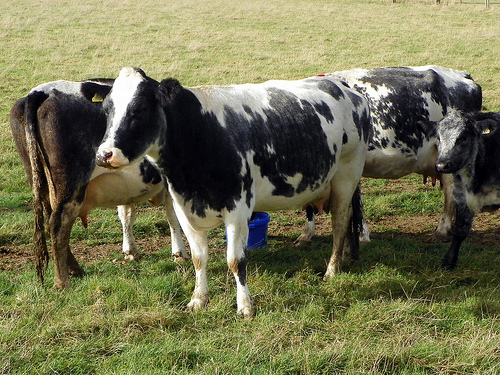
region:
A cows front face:
[81, 63, 171, 173]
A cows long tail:
[21, 97, 53, 283]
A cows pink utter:
[311, 195, 328, 214]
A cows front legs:
[166, 191, 266, 335]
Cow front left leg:
[218, 190, 262, 322]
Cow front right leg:
[173, 211, 213, 310]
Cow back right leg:
[38, 157, 83, 284]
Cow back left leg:
[313, 179, 359, 282]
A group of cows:
[0, 60, 499, 312]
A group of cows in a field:
[11, 66, 498, 319]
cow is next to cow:
[8, 79, 194, 288]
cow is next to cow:
[82, 65, 373, 322]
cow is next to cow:
[297, 63, 485, 274]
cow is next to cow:
[438, 103, 498, 270]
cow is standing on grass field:
[436, 96, 497, 275]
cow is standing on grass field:
[311, 63, 481, 276]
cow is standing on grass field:
[83, 66, 374, 324]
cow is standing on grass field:
[13, 79, 193, 290]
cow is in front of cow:
[79, 65, 376, 322]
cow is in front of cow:
[436, 101, 497, 267]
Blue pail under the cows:
[241, 208, 272, 247]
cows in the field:
[30, 40, 491, 252]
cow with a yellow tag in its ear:
[86, 92, 104, 108]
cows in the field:
[6, 35, 241, 279]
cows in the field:
[336, 33, 486, 230]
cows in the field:
[216, 63, 346, 286]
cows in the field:
[86, 59, 281, 309]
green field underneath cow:
[0, 2, 498, 373]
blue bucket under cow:
[245, 210, 280, 252]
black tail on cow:
[19, 89, 48, 290]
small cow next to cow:
[431, 105, 498, 272]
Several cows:
[7, 60, 499, 307]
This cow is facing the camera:
[77, 60, 217, 189]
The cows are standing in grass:
[27, 223, 481, 309]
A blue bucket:
[241, 209, 276, 248]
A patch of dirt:
[3, 237, 136, 261]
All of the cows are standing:
[17, 194, 498, 308]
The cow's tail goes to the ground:
[16, 93, 54, 284]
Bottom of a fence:
[397, 1, 499, 13]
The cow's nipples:
[301, 198, 338, 222]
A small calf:
[426, 108, 496, 286]